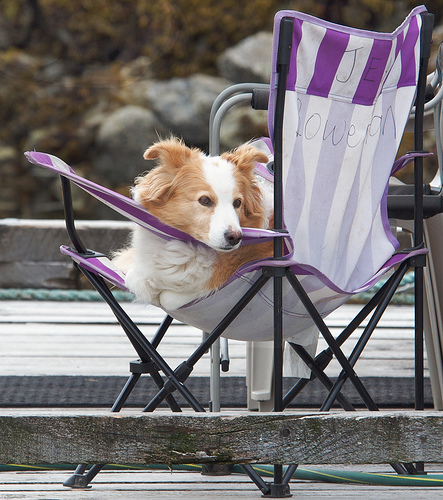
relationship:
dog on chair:
[130, 142, 289, 303] [24, 8, 430, 414]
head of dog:
[156, 138, 262, 253] [130, 142, 289, 303]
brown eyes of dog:
[198, 194, 242, 209] [130, 142, 289, 303]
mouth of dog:
[199, 205, 241, 254] [130, 142, 289, 303]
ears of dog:
[145, 142, 266, 176] [130, 142, 289, 303]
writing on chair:
[294, 31, 406, 151] [24, 8, 430, 414]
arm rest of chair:
[32, 146, 284, 255] [24, 8, 430, 414]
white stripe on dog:
[203, 151, 241, 237] [130, 142, 289, 303]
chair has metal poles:
[24, 8, 430, 414] [68, 283, 442, 498]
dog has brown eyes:
[130, 142, 289, 303] [193, 187, 242, 214]